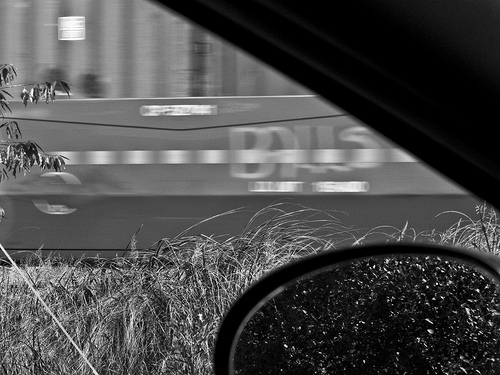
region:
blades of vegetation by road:
[451, 206, 493, 247]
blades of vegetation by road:
[202, 206, 309, 280]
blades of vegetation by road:
[145, 245, 202, 365]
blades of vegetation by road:
[53, 285, 125, 372]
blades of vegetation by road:
[4, 260, 52, 344]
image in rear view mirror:
[311, 258, 477, 373]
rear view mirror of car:
[196, 215, 498, 374]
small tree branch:
[4, 63, 78, 112]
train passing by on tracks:
[1, 58, 461, 293]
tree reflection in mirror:
[291, 297, 399, 356]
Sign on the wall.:
[54, 15, 87, 42]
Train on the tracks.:
[0, 95, 496, 269]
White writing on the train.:
[137, 103, 223, 119]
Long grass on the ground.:
[0, 205, 498, 374]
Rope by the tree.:
[0, 245, 112, 374]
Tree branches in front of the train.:
[1, 57, 73, 191]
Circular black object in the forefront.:
[205, 241, 496, 373]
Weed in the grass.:
[470, 201, 492, 248]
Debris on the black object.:
[237, 256, 497, 371]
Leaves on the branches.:
[17, 84, 74, 104]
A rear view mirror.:
[208, 239, 499, 374]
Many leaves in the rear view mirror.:
[271, 267, 499, 373]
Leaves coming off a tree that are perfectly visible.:
[0, 63, 70, 183]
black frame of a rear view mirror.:
[214, 243, 496, 371]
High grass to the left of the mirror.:
[0, 238, 215, 373]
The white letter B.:
[228, 123, 273, 179]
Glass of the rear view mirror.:
[240, 253, 499, 373]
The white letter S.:
[336, 124, 381, 171]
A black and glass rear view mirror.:
[214, 240, 496, 374]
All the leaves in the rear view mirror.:
[243, 258, 498, 372]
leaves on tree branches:
[12, 78, 83, 173]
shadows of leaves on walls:
[68, 65, 119, 102]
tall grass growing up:
[38, 243, 178, 331]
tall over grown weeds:
[43, 245, 176, 340]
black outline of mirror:
[230, 259, 315, 305]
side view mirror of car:
[222, 257, 480, 374]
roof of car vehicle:
[287, 0, 481, 195]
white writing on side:
[131, 93, 225, 121]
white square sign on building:
[48, 10, 91, 42]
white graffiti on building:
[217, 128, 392, 188]